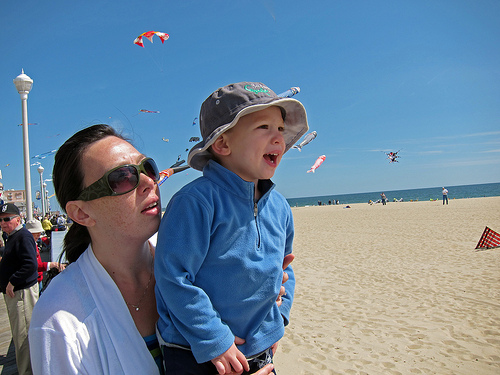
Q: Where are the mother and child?
A: On the beach.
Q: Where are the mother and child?
A: On the beach.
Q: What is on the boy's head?
A: A hat.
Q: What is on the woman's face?
A: Sunglasses.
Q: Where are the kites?
A: In the sky.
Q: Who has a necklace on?
A: The woman.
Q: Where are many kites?
A: In the air.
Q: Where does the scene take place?
A: At the beach.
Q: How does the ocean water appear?
A: Calm.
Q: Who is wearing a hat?
A: The boy.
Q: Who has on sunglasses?
A: The woman.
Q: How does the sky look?
A: Blue with a few clouds.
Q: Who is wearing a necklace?
A: The lady.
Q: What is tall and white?
A: Street lamp.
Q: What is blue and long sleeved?
A: Boy's sweater.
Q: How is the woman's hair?
A: In a ponytail.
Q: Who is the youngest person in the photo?
A: The one wearing a hat.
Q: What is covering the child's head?
A: A hat.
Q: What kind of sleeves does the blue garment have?
A: Long sleeves.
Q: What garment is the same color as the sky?
A: The boy's shirt.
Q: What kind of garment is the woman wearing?
A: A sweater.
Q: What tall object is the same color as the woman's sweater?
A: The light post.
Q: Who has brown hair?
A: The woman.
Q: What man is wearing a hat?
A: The man in the background.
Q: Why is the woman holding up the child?
A: For a better view.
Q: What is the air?
A: Kites.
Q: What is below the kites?
A: The beach.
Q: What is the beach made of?
A: Sand.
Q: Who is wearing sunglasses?
A: The mother.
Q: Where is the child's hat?
A: On his head.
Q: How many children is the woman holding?
A: One.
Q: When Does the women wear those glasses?
A: Sunny days.